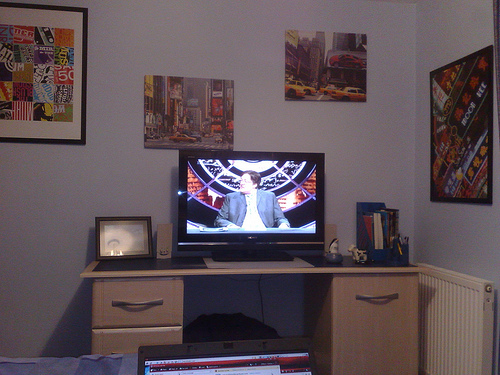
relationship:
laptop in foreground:
[143, 336, 313, 373] [1, 308, 485, 373]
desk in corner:
[86, 234, 471, 362] [294, 1, 482, 371]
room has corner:
[19, 16, 497, 353] [294, 1, 482, 371]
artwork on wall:
[427, 40, 489, 207] [0, 4, 500, 351]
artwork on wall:
[282, 30, 367, 105] [0, 4, 500, 351]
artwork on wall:
[141, 75, 236, 149] [0, 4, 500, 351]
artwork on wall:
[5, 5, 92, 142] [0, 4, 500, 351]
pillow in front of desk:
[1, 347, 137, 373] [76, 251, 415, 340]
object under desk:
[182, 303, 282, 342] [77, 246, 421, 372]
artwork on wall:
[0, 2, 90, 146] [0, 0, 416, 357]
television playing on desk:
[179, 149, 324, 249] [77, 246, 421, 372]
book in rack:
[361, 212, 373, 244] [354, 200, 413, 268]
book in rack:
[372, 211, 384, 251] [354, 200, 413, 268]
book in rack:
[380, 204, 390, 250] [354, 200, 413, 268]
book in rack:
[382, 204, 400, 251] [354, 200, 413, 268]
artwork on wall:
[0, 2, 90, 146] [0, 4, 500, 351]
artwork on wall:
[427, 43, 494, 206] [0, 4, 500, 351]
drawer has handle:
[86, 275, 187, 332] [107, 296, 165, 308]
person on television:
[213, 168, 293, 232] [172, 138, 334, 255]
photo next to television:
[88, 211, 160, 261] [172, 138, 334, 255]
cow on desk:
[343, 242, 369, 265] [72, 262, 431, 287]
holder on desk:
[360, 205, 388, 267] [77, 246, 421, 372]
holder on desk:
[393, 237, 413, 263] [77, 246, 421, 372]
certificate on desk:
[92, 211, 156, 258] [77, 246, 421, 372]